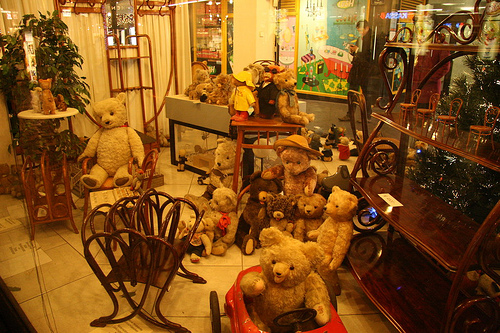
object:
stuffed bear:
[236, 223, 332, 326]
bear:
[206, 73, 234, 105]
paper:
[376, 194, 404, 209]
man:
[336, 19, 382, 125]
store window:
[263, 5, 500, 110]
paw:
[81, 176, 98, 190]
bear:
[78, 92, 146, 190]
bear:
[261, 134, 324, 196]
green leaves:
[42, 42, 92, 119]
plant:
[0, 12, 93, 156]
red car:
[205, 263, 351, 333]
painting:
[291, 0, 365, 104]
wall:
[231, 0, 303, 113]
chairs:
[398, 90, 425, 122]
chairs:
[414, 93, 444, 128]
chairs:
[433, 97, 466, 139]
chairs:
[465, 105, 496, 151]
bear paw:
[248, 277, 267, 296]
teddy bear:
[304, 189, 367, 271]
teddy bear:
[244, 194, 300, 253]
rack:
[78, 183, 218, 333]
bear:
[237, 229, 330, 333]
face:
[262, 243, 310, 287]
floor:
[6, 143, 408, 333]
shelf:
[343, 10, 499, 333]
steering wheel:
[274, 307, 318, 327]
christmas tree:
[409, 50, 500, 222]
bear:
[294, 194, 329, 242]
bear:
[199, 183, 242, 257]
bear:
[271, 71, 315, 124]